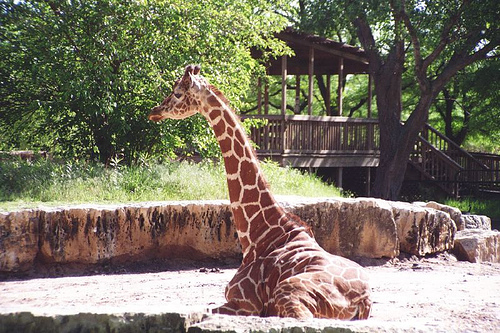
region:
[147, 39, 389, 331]
A giraffe sitting on the ground.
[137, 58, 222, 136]
The giraffe's head.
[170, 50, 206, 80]
Horns on giraffe's head.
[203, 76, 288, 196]
Brown mane on giraffe's neck.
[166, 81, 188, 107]
A giraffe's left eye.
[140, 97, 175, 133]
A giraffe's nose.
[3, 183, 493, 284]
A long stone wall.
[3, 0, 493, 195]
Green trees in the background.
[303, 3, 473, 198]
The trunk of a tall tree.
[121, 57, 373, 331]
A giraffe inside an enclosure.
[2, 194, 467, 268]
dirty brown and black stone embankment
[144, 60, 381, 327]
tan and brown giraffe laying down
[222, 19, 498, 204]
brown wooden structure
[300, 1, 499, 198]
tall leafy tree with a thick trunk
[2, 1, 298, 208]
short bushy green tree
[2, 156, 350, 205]
dense green overgrown grass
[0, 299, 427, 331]
large rectangular stone blocks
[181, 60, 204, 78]
fuzzy little brown giraffe horns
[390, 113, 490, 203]
brown wooden stair case with railings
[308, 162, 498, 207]
metal mesh fenceing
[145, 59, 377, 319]
giraffe resting beside wall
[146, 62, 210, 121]
head of sitting giraffe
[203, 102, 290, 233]
long neck of sitting giraffe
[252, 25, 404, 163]
gazebo next to giraffe area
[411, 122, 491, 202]
wooden stairs into gazebo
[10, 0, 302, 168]
tree beside wooden gazebo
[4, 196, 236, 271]
rock wall near giraffe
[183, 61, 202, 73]
two horns on giraffe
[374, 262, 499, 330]
ground on which giraffe is sitting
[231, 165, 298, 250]
brown spots on giraffe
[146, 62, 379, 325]
Giraffe is sitting down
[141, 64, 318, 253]
giraffe has long neck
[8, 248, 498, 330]
giraffe sitting in dirt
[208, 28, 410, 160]
wooden gazebo is behind giraffe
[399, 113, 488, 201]
gazebo has wooden stairs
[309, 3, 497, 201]
leafy tree in front of gazebo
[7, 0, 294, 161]
leafy bush behind giraffe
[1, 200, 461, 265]
rock ledge behind giraffe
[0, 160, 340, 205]
hill is behind giraffe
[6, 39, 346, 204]
bush is on grassy hill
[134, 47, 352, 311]
giraffe is sitting down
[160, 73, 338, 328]
giraffe sits on ground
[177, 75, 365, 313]
giraffe has brown and white spots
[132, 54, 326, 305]
giraffe's neck is extended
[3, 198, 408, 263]
brown rocks behind giraffe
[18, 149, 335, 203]
tall green grass behind rocks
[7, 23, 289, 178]
tall, leafy trees behind grasses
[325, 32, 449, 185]
thick trunk on tree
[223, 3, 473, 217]
wooden viewing post behind giraffe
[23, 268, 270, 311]
ground is brown and dead